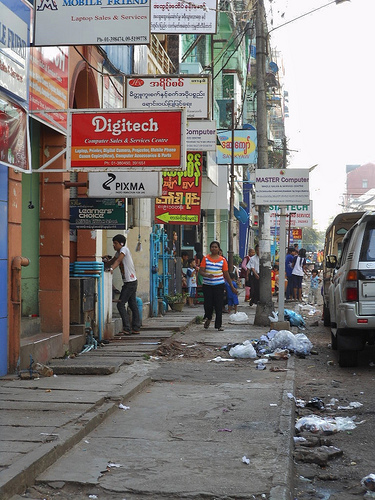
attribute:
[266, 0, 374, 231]
sky — white, daytime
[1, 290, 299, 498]
sidewalk — grey, dirty, uneven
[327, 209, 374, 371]
car — parked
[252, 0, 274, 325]
pole — grey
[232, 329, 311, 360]
garbage — here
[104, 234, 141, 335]
man — leaning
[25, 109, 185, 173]
sign — red, orange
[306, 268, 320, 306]
child — standing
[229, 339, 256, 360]
bag — here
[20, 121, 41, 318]
door — green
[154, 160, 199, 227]
sign — yellow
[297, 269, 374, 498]
road — here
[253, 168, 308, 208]
sign — white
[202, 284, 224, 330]
pants — black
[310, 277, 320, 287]
shirt — blue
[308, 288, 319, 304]
pants — white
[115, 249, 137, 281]
shirt — white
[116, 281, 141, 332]
pants — black